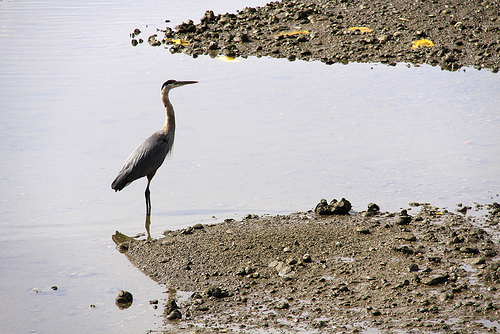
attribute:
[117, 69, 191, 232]
crane — one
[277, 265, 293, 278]
stone — small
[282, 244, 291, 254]
stone — small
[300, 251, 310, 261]
stone — small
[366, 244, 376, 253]
stone — small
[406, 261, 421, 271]
stone — small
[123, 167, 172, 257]
legs — long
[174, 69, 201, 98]
beak — long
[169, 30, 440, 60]
spots — orange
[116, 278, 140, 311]
rock — small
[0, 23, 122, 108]
ripples — small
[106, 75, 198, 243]
bird — crane